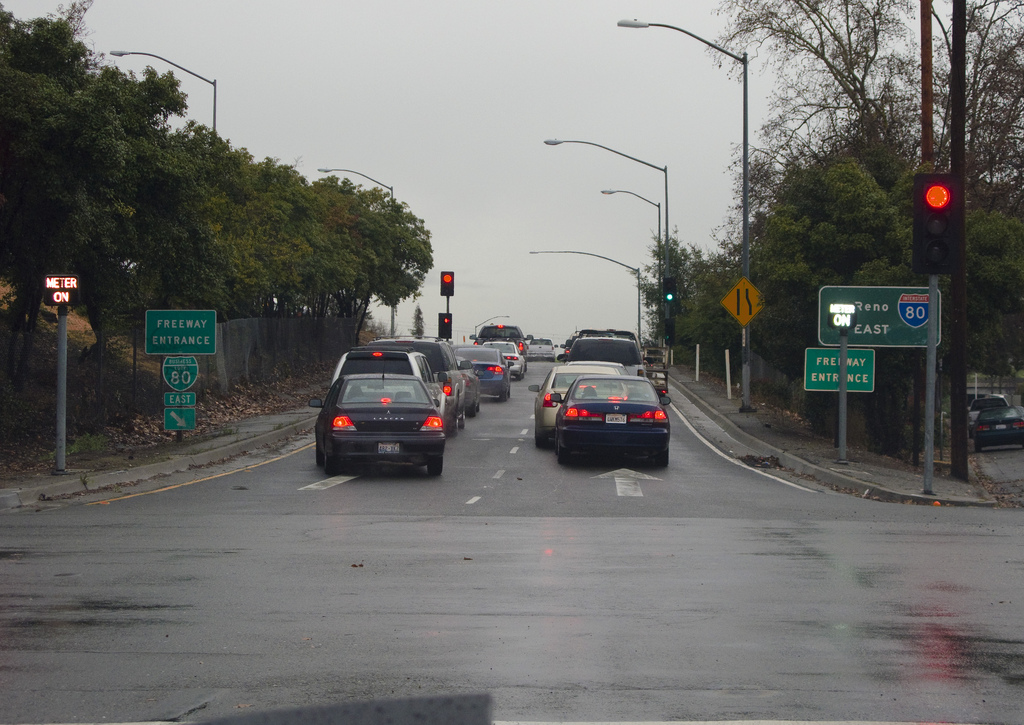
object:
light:
[912, 171, 966, 274]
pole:
[920, 259, 940, 495]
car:
[555, 375, 670, 466]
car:
[315, 358, 446, 476]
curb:
[663, 363, 995, 509]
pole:
[57, 303, 73, 471]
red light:
[329, 415, 354, 430]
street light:
[925, 182, 949, 210]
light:
[616, 19, 751, 414]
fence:
[77, 315, 362, 428]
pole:
[920, 0, 936, 174]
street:
[0, 359, 1024, 725]